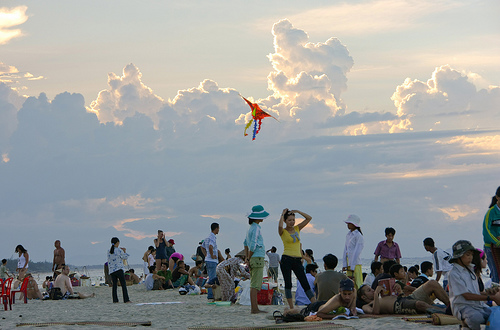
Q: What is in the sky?
A: Clouds.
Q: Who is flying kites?
A: People.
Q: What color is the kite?
A: Red, blue, and yellow.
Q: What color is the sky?
A: Grey.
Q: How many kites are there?
A: One.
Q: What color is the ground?
A: Brown.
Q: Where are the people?
A: Beach.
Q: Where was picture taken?
A: On a beach.